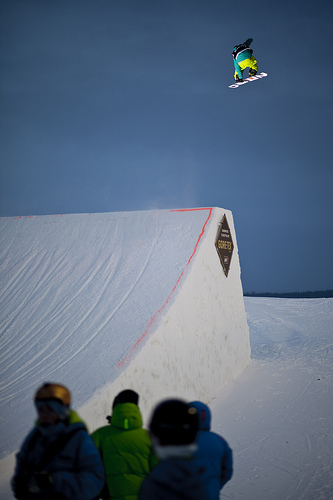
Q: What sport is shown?
A: Snowboarding.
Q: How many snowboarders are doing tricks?
A: 1.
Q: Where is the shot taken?
A: Crowd.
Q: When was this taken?
A: Daytime.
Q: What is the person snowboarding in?
A: Half pipe.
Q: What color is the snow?
A: White.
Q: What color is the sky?
A: Blue.